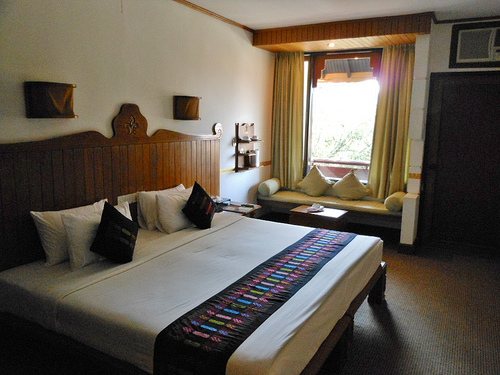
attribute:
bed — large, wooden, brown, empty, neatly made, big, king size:
[1, 103, 387, 374]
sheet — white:
[2, 182, 384, 374]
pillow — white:
[34, 198, 110, 269]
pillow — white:
[137, 180, 187, 234]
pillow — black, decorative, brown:
[184, 181, 215, 225]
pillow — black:
[91, 202, 137, 265]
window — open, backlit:
[308, 51, 381, 181]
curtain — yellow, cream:
[270, 43, 415, 201]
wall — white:
[1, 1, 276, 223]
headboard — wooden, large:
[1, 103, 221, 273]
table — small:
[222, 199, 259, 219]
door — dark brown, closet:
[417, 69, 497, 253]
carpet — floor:
[249, 210, 495, 374]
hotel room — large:
[1, 2, 500, 373]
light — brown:
[23, 79, 77, 118]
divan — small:
[258, 177, 283, 197]